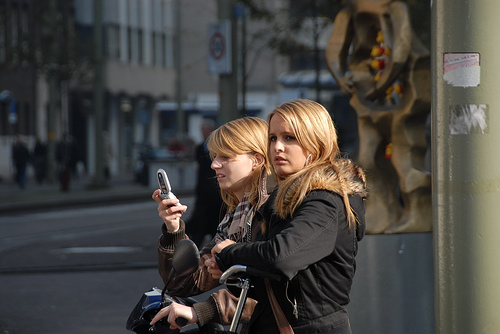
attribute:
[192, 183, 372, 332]
jacket — black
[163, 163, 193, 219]
phone — silver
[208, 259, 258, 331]
bar — silver, metal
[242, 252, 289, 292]
handle — black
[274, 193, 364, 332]
jacket — brown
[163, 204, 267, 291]
jacket — leather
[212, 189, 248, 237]
scarf — blue, white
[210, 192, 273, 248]
scarf — black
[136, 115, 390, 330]
ladies — blonde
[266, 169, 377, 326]
coat — black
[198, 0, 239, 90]
sign — square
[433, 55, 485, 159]
stickers — old, torn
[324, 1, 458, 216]
figure — metal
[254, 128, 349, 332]
coat — black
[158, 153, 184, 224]
phone — grey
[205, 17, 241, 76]
sign — White 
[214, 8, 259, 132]
pole — wooden street 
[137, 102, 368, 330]
girls — both 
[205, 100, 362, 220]
hair — strawberry blond 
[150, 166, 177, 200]
phone — silver cell 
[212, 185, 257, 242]
scarf — plaid 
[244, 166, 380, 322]
jacket — brown 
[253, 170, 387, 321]
jacket — black  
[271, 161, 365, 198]
trim — fur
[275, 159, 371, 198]
trim — fur, brown tan , black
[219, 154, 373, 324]
jacket — black  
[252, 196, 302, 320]
strap —  brown leather 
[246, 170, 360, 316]
body —  her 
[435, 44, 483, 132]
stickers —  two ,  pealed off 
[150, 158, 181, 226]
phone — cell 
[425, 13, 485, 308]
post — grey metal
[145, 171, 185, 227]
cell phone — flip style, grey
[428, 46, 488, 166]
sticker — peeling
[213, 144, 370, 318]
jacket — black, fur trimmed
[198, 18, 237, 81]
sign — white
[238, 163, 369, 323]
jacket — black  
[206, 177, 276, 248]
shirt — plaid patterned